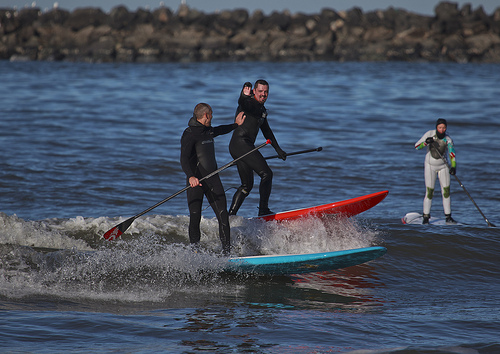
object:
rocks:
[226, 32, 255, 47]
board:
[208, 245, 390, 275]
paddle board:
[248, 190, 387, 225]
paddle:
[264, 147, 321, 161]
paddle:
[103, 139, 272, 242]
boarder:
[227, 79, 288, 218]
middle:
[227, 24, 286, 273]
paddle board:
[401, 211, 492, 229]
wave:
[0, 204, 380, 306]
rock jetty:
[0, 0, 500, 63]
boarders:
[179, 102, 245, 258]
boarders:
[413, 117, 457, 225]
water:
[0, 60, 500, 354]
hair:
[193, 103, 211, 120]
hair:
[254, 79, 270, 91]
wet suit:
[228, 83, 288, 214]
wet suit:
[179, 118, 240, 254]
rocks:
[464, 32, 496, 57]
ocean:
[1, 59, 500, 354]